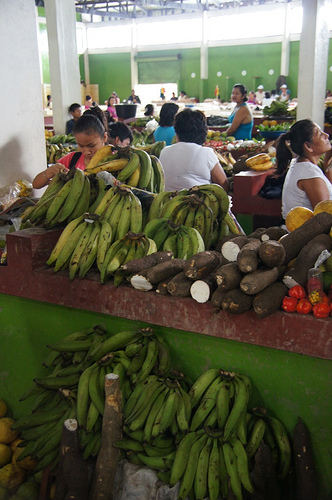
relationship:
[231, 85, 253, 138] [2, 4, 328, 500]
person in a market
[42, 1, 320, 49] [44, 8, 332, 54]
sun through windows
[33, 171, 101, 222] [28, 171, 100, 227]
bunch of bananas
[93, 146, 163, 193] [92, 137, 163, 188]
bunch of bananas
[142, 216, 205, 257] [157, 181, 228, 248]
bunch of bananas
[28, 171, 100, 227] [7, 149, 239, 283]
bananas on display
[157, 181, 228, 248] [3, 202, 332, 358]
bananas on a table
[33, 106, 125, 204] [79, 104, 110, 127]
woman with a pony tail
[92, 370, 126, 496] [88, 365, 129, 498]
stick of stick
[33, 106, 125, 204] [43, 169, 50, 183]
woman wearing a bracelet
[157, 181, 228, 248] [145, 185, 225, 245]
bunch of banana